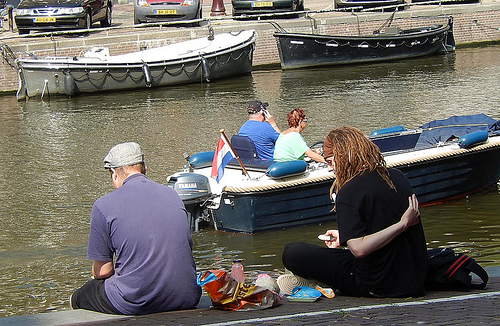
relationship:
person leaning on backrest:
[235, 103, 277, 162] [223, 135, 262, 157]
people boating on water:
[235, 98, 329, 165] [1, 42, 498, 315]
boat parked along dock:
[1, 27, 259, 97] [4, 6, 485, 89]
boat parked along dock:
[275, 18, 461, 68] [4, 6, 485, 89]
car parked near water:
[12, 0, 114, 38] [1, 42, 498, 315]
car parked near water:
[131, 0, 203, 26] [1, 42, 498, 315]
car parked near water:
[229, 0, 305, 21] [1, 42, 498, 315]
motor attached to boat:
[163, 176, 229, 234] [163, 112, 498, 239]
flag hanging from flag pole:
[202, 127, 253, 181] [218, 127, 256, 183]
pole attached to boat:
[206, 128, 248, 189] [174, 129, 495, 217]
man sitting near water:
[68, 141, 207, 318] [1, 42, 498, 315]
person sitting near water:
[271, 114, 438, 294] [1, 42, 498, 315]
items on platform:
[196, 257, 335, 312] [0, 260, 498, 324]